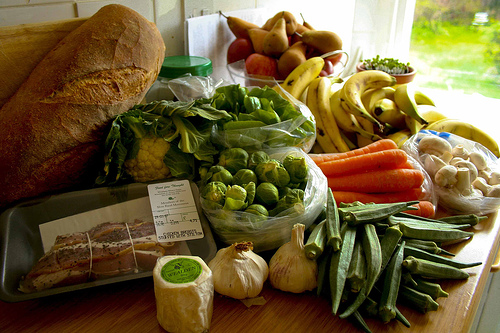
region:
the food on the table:
[0, 2, 499, 332]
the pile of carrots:
[310, 139, 436, 217]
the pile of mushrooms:
[419, 132, 499, 202]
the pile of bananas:
[272, 58, 498, 158]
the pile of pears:
[220, 9, 338, 71]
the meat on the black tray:
[1, 182, 212, 292]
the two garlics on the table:
[208, 222, 318, 302]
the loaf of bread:
[4, 4, 165, 204]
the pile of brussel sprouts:
[196, 146, 321, 241]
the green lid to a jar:
[160, 52, 212, 78]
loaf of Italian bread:
[3, 1, 167, 194]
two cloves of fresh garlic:
[214, 231, 319, 298]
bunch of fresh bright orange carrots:
[318, 140, 430, 208]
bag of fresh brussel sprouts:
[201, 145, 316, 237]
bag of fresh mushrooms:
[421, 135, 493, 200]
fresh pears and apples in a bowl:
[223, 12, 344, 79]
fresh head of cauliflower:
[109, 100, 202, 188]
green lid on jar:
[158, 53, 211, 80]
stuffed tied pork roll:
[17, 215, 197, 292]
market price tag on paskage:
[151, 177, 199, 244]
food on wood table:
[2, 6, 497, 330]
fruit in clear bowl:
[223, 10, 342, 87]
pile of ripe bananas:
[281, 56, 417, 141]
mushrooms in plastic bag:
[404, 128, 499, 205]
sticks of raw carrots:
[323, 138, 428, 207]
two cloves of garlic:
[213, 223, 316, 300]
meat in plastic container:
[0, 180, 216, 304]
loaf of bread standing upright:
[1, 4, 160, 191]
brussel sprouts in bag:
[204, 143, 326, 243]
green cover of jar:
[162, 54, 214, 80]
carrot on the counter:
[320, 151, 400, 168]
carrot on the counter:
[338, 176, 412, 191]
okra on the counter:
[331, 234, 348, 309]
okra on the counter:
[398, 258, 458, 277]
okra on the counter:
[360, 224, 376, 294]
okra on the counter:
[400, 225, 462, 242]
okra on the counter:
[352, 207, 414, 219]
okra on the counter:
[385, 243, 396, 328]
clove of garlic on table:
[226, 249, 261, 297]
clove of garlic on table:
[267, 227, 317, 295]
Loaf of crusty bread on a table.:
[0, 3, 165, 202]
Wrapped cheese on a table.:
[152, 254, 214, 331]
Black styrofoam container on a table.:
[0, 179, 219, 302]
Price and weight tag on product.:
[146, 178, 204, 243]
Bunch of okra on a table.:
[302, 186, 488, 331]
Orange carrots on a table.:
[307, 138, 435, 218]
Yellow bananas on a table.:
[271, 57, 498, 158]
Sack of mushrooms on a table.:
[402, 128, 499, 216]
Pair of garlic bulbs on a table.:
[207, 222, 317, 307]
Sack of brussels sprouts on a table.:
[199, 145, 328, 251]